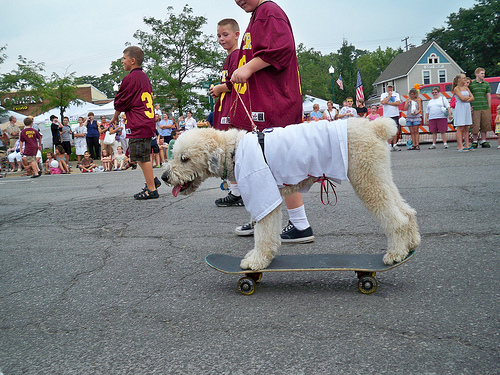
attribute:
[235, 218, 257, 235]
sneaker — white, black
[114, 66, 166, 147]
jersey — maroon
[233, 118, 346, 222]
t-shirt — white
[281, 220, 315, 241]
sneaker — black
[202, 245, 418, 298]
skateboard — black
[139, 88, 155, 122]
3 — yellow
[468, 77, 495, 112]
shirt — green, striped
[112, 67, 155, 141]
jersey — maroon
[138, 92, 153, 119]
number — yellow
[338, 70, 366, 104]
flags — American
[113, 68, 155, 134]
jersey — maroon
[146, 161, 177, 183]
nose — black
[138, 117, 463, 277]
dog — patient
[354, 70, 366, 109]
flag — american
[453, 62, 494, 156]
couple — lovely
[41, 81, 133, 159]
tents — white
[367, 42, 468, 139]
house — tan, blue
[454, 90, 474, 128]
sundress — white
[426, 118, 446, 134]
shorts — pink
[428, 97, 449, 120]
top — white